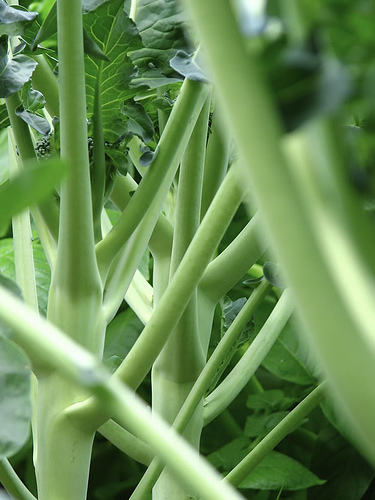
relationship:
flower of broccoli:
[31, 135, 52, 158] [33, 132, 95, 166]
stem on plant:
[51, 0, 104, 298] [76, 16, 193, 138]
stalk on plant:
[163, 90, 216, 303] [2, 0, 372, 496]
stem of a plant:
[32, 3, 103, 499] [88, 64, 358, 336]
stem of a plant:
[32, 3, 103, 499] [1, 1, 254, 499]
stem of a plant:
[32, 3, 103, 499] [173, 1, 372, 469]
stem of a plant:
[51, 0, 104, 298] [2, 0, 372, 496]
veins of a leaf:
[101, 43, 117, 107] [73, 6, 140, 149]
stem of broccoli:
[28, 293, 108, 499] [29, 8, 131, 485]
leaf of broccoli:
[215, 437, 338, 493] [2, 2, 368, 492]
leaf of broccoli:
[241, 299, 344, 397] [2, 2, 368, 492]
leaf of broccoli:
[239, 375, 293, 417] [2, 2, 368, 492]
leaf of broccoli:
[227, 410, 311, 445] [2, 2, 368, 492]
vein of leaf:
[102, 76, 121, 109] [0, 33, 32, 97]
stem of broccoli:
[51, 0, 104, 298] [2, 2, 368, 492]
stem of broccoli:
[148, 162, 206, 496] [2, 2, 368, 492]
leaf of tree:
[81, 0, 145, 145] [1, 1, 372, 497]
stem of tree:
[28, 372, 99, 498] [2, 121, 335, 498]